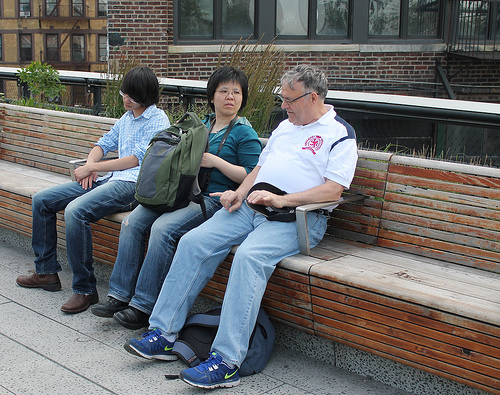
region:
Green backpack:
[125, 107, 219, 216]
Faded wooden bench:
[360, 146, 498, 382]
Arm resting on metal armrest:
[244, 170, 360, 224]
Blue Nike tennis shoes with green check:
[119, 323, 270, 391]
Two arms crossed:
[61, 136, 146, 191]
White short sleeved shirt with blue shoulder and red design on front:
[244, 113, 388, 216]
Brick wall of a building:
[112, 7, 161, 55]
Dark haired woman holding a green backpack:
[132, 61, 264, 232]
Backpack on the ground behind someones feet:
[156, 297, 273, 384]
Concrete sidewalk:
[8, 318, 93, 378]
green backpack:
[132, 114, 207, 216]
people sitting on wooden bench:
[19, 63, 364, 392]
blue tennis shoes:
[120, 325, 239, 392]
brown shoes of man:
[14, 265, 103, 317]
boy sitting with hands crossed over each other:
[14, 60, 168, 317]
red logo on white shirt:
[298, 130, 328, 158]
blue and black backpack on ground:
[167, 301, 277, 384]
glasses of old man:
[277, 86, 322, 107]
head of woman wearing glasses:
[205, 64, 251, 119]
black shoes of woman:
[88, 292, 153, 334]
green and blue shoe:
[168, 351, 246, 386]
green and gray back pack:
[118, 105, 205, 243]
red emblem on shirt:
[291, 125, 346, 173]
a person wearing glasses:
[97, 57, 173, 123]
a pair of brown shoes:
[11, 257, 122, 352]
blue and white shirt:
[78, 102, 173, 193]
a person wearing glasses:
[250, 65, 334, 140]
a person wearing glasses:
[183, 72, 258, 127]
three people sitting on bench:
[9, 69, 375, 336]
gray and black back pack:
[128, 299, 296, 384]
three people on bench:
[47, 66, 336, 313]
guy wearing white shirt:
[256, 61, 367, 223]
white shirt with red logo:
[261, 101, 377, 226]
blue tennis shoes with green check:
[72, 325, 277, 392]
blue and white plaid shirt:
[93, 64, 176, 186]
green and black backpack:
[142, 110, 219, 213]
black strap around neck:
[209, 70, 251, 220]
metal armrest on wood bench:
[289, 174, 404, 286]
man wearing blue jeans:
[54, 64, 166, 314]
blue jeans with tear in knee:
[113, 193, 174, 270]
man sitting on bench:
[136, 62, 362, 392]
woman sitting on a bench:
[96, 62, 258, 324]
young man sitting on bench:
[13, 64, 170, 319]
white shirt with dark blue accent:
[261, 105, 357, 212]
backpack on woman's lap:
[132, 109, 210, 210]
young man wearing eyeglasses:
[20, 62, 174, 324]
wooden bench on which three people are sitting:
[1, 97, 498, 393]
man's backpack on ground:
[170, 298, 281, 379]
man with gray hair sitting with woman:
[91, 65, 371, 393]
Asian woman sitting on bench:
[88, 65, 262, 330]